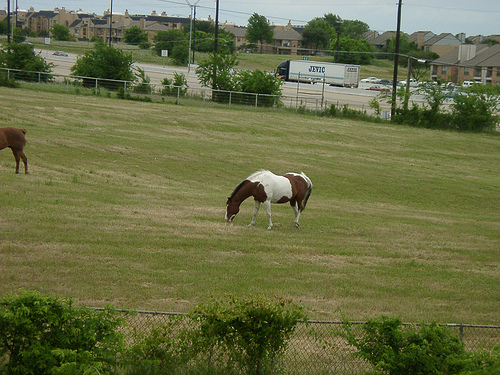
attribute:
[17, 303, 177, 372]
bush fence — green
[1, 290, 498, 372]
plants — green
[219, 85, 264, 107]
fence — metal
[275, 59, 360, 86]
truck — blue, white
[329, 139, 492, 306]
grass — green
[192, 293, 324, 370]
bush — green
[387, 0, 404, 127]
telephone pole — wood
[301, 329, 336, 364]
fence — grey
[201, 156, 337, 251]
horse — brown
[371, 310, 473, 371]
bush — green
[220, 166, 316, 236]
horse — white, brown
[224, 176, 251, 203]
mane — black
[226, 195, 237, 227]
face — white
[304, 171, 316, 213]
tail — long